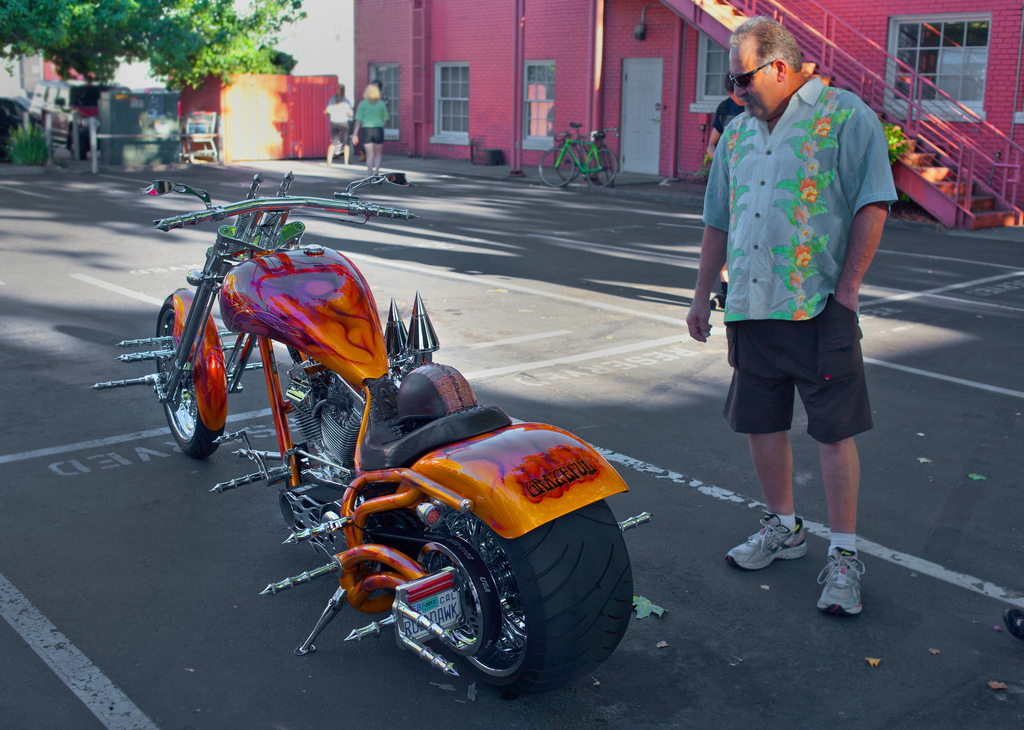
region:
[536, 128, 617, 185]
A green bicycle by a grey door.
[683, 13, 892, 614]
Man wearing shorts and sunglasses looking at a motorcycle.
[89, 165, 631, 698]
A multicolored motorcycle with spikes.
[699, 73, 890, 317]
Shirt with flowers the man in sunglasses is wearing.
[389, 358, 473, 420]
The helmet on the seat of the motorcycle.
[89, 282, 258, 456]
Front motorcycle wheel with spikes.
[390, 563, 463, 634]
License plate on the motorcycle.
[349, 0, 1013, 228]
Pink brick building across from the motorcycle.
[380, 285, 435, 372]
Two large spikes in front of motorcycle seat.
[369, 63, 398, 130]
a window on a building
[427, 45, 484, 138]
a window on a building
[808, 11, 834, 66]
a window on a building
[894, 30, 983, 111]
a window on a building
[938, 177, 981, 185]
a step on a stairway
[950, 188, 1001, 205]
a step on a stairway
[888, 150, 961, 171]
a step on a stairway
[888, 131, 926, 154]
a step on a stairway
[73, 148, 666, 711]
the motorcycle is orange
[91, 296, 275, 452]
front wheel of a motorcycle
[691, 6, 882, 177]
the hair is gray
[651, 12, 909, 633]
the pants are black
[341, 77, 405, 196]
the woman is blonde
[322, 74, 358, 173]
the man has white shirt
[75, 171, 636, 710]
A motorcycle is painted orange with flames.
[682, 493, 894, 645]
The man is wearing a pair of white sneakers.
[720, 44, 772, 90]
The man is wearing a pair of sunglasses.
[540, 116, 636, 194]
A green bike is parked on the side of the road.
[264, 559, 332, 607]
spike on a motorcycle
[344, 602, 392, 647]
spike on a motorcycle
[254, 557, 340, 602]
spike on a motorcycle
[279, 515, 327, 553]
spike on a motorcycle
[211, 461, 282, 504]
spike on a motorcycle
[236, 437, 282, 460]
spike on a motorcycle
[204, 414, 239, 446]
spike on a motorcycle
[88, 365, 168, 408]
spike on a motorcycle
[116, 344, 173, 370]
spike on a motorcycle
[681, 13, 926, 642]
man wearing a shirt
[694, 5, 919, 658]
man wearing green shirts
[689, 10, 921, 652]
man wearing tennis shoes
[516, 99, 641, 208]
bike near a building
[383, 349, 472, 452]
helmet on a cycle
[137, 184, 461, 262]
bars on a cycle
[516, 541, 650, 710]
tire on a cycle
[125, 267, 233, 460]
tire on a cycle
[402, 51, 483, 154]
window on a building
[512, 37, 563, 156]
window on a building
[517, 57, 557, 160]
A window on a building.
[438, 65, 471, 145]
A window on a building.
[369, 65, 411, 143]
A window on a building.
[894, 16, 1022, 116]
A window on a building.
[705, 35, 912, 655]
A person is standing up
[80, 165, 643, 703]
custom painted motorcycle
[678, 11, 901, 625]
man is wearing a patterned shirt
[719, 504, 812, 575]
right running shoe with laces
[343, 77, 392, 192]
person in a green shirt is walking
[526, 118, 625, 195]
green bicycle leans against a wall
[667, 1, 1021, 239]
red metal staircase outside a building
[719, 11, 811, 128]
man is wearing sunglasses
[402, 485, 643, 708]
wide back motorcycle tire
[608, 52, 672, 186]
white door in a red building